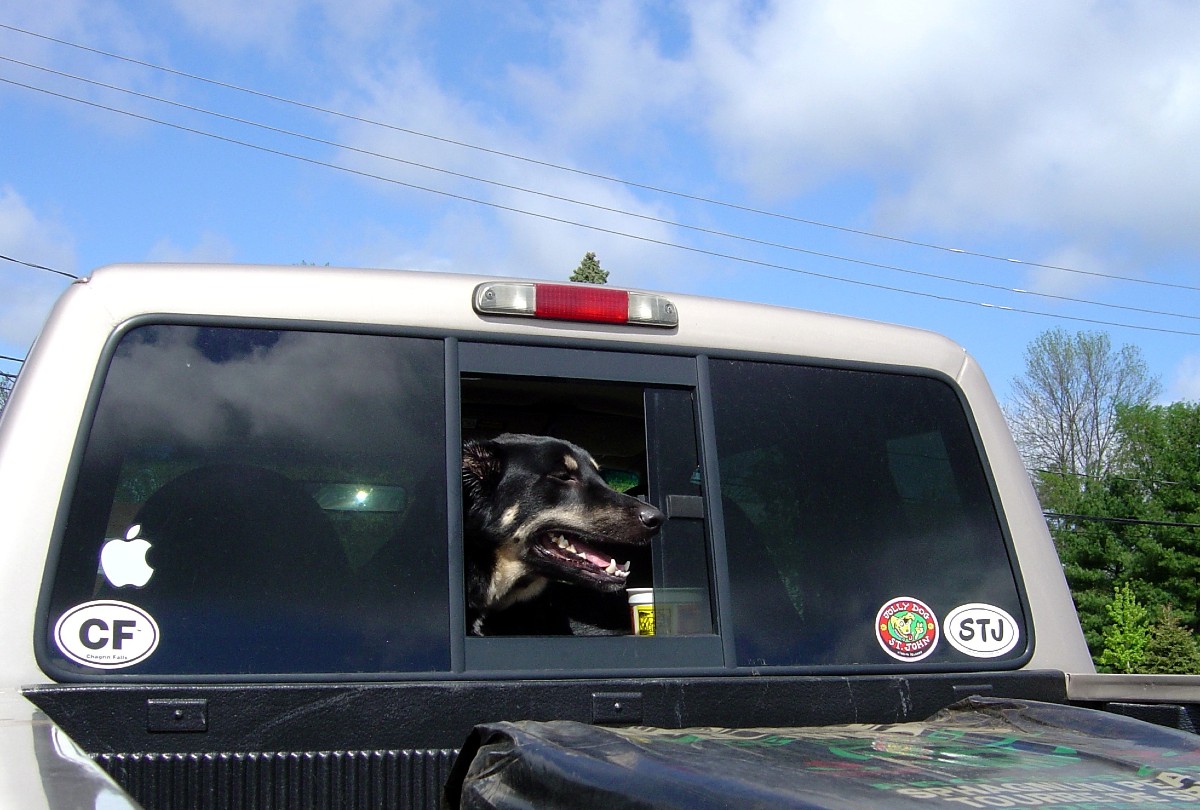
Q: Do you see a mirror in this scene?
A: Yes, there is a mirror.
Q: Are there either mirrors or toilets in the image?
A: Yes, there is a mirror.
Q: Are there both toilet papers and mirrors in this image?
A: No, there is a mirror but no toilet papers.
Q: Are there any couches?
A: No, there are no couches.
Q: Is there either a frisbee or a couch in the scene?
A: No, there are no couches or frisbees.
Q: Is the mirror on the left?
A: Yes, the mirror is on the left of the image.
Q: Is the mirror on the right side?
A: No, the mirror is on the left of the image.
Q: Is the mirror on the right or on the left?
A: The mirror is on the left of the image.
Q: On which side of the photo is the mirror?
A: The mirror is on the left of the image.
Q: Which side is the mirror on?
A: The mirror is on the left of the image.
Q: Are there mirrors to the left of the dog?
A: Yes, there is a mirror to the left of the dog.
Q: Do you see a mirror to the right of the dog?
A: No, the mirror is to the left of the dog.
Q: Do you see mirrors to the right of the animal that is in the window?
A: No, the mirror is to the left of the dog.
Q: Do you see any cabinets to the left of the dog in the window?
A: No, there is a mirror to the left of the dog.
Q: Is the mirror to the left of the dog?
A: Yes, the mirror is to the left of the dog.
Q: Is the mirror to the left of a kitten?
A: No, the mirror is to the left of the dog.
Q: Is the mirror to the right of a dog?
A: No, the mirror is to the left of a dog.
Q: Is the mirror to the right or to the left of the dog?
A: The mirror is to the left of the dog.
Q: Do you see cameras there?
A: No, there are no cameras.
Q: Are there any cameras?
A: No, there are no cameras.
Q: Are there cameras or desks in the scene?
A: No, there are no cameras or desks.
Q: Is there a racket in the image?
A: No, there are no rackets.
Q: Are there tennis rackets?
A: No, there are no tennis rackets.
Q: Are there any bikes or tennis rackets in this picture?
A: No, there are no tennis rackets or bikes.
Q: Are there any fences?
A: No, there are no fences.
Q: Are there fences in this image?
A: No, there are no fences.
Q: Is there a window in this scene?
A: Yes, there is a window.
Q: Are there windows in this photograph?
A: Yes, there is a window.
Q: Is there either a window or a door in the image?
A: Yes, there is a window.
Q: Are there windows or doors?
A: Yes, there is a window.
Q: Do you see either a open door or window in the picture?
A: Yes, there is an open window.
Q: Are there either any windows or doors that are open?
A: Yes, the window is open.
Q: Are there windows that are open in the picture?
A: Yes, there is an open window.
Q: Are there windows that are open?
A: Yes, there is a window that is open.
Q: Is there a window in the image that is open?
A: Yes, there is a window that is open.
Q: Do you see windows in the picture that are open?
A: Yes, there is a window that is open.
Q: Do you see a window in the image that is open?
A: Yes, there is a window that is open.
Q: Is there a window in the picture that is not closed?
A: Yes, there is a open window.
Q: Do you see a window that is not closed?
A: Yes, there is a open window.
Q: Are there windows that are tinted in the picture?
A: Yes, there is a tinted window.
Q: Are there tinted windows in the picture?
A: Yes, there is a tinted window.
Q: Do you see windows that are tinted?
A: Yes, there is a tinted window.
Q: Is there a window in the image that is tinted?
A: Yes, there is a window that is tinted.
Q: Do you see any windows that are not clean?
A: Yes, there is a tinted window.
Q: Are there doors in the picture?
A: No, there are no doors.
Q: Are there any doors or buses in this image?
A: No, there are no doors or buses.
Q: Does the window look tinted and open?
A: Yes, the window is tinted and open.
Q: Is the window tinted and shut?
A: No, the window is tinted but open.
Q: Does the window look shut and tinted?
A: No, the window is tinted but open.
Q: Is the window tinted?
A: Yes, the window is tinted.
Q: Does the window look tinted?
A: Yes, the window is tinted.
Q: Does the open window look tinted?
A: Yes, the window is tinted.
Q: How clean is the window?
A: The window is tinted.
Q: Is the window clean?
A: No, the window is tinted.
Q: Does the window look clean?
A: No, the window is tinted.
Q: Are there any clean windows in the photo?
A: No, there is a window but it is tinted.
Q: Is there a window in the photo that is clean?
A: No, there is a window but it is tinted.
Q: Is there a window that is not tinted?
A: No, there is a window but it is tinted.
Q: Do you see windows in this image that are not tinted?
A: No, there is a window but it is tinted.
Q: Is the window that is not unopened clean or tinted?
A: The window is tinted.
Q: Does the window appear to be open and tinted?
A: Yes, the window is open and tinted.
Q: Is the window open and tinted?
A: Yes, the window is open and tinted.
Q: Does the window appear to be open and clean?
A: No, the window is open but tinted.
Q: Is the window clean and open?
A: No, the window is open but tinted.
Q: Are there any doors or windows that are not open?
A: No, there is a window but it is open.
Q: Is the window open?
A: Yes, the window is open.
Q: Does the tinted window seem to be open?
A: Yes, the window is open.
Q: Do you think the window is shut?
A: No, the window is open.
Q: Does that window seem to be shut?
A: No, the window is open.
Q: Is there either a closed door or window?
A: No, there is a window but it is open.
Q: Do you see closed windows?
A: No, there is a window but it is open.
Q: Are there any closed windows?
A: No, there is a window but it is open.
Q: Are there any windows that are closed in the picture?
A: No, there is a window but it is open.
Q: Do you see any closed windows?
A: No, there is a window but it is open.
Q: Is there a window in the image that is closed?
A: No, there is a window but it is open.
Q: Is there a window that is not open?
A: No, there is a window but it is open.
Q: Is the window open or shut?
A: The window is open.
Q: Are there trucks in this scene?
A: Yes, there is a truck.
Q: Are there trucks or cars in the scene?
A: Yes, there is a truck.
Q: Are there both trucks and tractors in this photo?
A: No, there is a truck but no tractors.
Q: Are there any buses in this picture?
A: No, there are no buses.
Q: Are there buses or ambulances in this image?
A: No, there are no buses or ambulances.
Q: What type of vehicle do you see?
A: The vehicle is a truck.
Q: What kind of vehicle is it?
A: The vehicle is a truck.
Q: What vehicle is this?
A: This is a truck.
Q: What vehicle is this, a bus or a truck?
A: This is a truck.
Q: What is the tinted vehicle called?
A: The vehicle is a truck.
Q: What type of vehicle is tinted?
A: The vehicle is a truck.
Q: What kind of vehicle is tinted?
A: The vehicle is a truck.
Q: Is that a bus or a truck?
A: That is a truck.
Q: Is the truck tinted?
A: Yes, the truck is tinted.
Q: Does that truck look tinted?
A: Yes, the truck is tinted.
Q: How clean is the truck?
A: The truck is tinted.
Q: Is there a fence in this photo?
A: No, there are no fences.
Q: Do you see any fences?
A: No, there are no fences.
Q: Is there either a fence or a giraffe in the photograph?
A: No, there are no fences or giraffes.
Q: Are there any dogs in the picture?
A: Yes, there is a dog.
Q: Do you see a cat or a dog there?
A: Yes, there is a dog.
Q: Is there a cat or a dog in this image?
A: Yes, there is a dog.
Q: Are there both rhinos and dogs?
A: No, there is a dog but no rhinos.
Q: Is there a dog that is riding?
A: Yes, there is a dog that is riding.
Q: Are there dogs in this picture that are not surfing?
A: Yes, there is a dog that is riding.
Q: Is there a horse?
A: No, there are no horses.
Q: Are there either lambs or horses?
A: No, there are no horses or lambs.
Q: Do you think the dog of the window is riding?
A: Yes, the dog is riding.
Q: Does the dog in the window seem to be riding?
A: Yes, the dog is riding.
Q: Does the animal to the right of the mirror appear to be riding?
A: Yes, the dog is riding.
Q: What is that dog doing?
A: The dog is riding.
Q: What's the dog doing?
A: The dog is riding.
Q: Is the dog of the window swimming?
A: No, the dog is riding.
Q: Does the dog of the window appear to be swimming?
A: No, the dog is riding.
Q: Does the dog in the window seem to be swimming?
A: No, the dog is riding.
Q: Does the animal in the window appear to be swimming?
A: No, the dog is riding.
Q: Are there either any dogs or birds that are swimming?
A: No, there is a dog but it is riding.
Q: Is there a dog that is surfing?
A: No, there is a dog but it is riding.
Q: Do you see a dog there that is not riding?
A: No, there is a dog but it is riding.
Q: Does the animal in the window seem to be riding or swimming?
A: The dog is riding.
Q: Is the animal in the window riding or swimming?
A: The dog is riding.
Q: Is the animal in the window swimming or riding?
A: The dog is riding.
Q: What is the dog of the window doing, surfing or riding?
A: The dog is riding.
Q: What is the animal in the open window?
A: The animal is a dog.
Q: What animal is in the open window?
A: The animal is a dog.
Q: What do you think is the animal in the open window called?
A: The animal is a dog.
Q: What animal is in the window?
A: The animal is a dog.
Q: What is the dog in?
A: The dog is in the window.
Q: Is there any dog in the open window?
A: Yes, there is a dog in the window.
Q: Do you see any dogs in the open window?
A: Yes, there is a dog in the window.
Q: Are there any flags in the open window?
A: No, there is a dog in the window.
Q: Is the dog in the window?
A: Yes, the dog is in the window.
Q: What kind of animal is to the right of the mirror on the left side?
A: The animal is a dog.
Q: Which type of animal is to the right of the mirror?
A: The animal is a dog.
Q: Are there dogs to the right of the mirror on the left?
A: Yes, there is a dog to the right of the mirror.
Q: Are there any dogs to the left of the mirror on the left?
A: No, the dog is to the right of the mirror.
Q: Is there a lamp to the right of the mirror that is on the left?
A: No, there is a dog to the right of the mirror.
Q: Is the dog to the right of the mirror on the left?
A: Yes, the dog is to the right of the mirror.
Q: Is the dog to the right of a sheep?
A: No, the dog is to the right of the mirror.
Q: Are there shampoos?
A: No, there are no shampoos.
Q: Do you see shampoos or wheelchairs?
A: No, there are no shampoos or wheelchairs.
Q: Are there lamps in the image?
A: No, there are no lamps.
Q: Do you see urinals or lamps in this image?
A: No, there are no lamps or urinals.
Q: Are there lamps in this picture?
A: No, there are no lamps.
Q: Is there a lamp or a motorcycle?
A: No, there are no lamps or motorcycles.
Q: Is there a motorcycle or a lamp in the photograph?
A: No, there are no lamps or motorcycles.